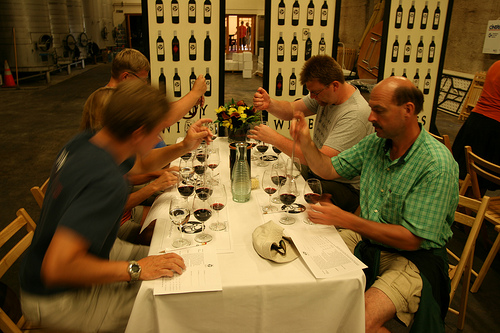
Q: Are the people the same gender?
A: No, they are both male and female.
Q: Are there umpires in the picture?
A: No, there are no umpires.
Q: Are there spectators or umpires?
A: No, there are no umpires or spectators.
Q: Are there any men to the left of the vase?
A: Yes, there is a man to the left of the vase.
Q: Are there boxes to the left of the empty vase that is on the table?
A: No, there is a man to the left of the vase.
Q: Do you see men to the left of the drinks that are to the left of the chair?
A: Yes, there is a man to the left of the drinks.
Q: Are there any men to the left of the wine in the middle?
A: Yes, there is a man to the left of the wine.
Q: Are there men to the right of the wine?
A: No, the man is to the left of the wine.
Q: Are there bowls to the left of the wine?
A: No, there is a man to the left of the wine.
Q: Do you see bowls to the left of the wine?
A: No, there is a man to the left of the wine.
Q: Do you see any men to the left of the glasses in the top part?
A: Yes, there is a man to the left of the glasses.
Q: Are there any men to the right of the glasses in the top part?
A: No, the man is to the left of the glasses.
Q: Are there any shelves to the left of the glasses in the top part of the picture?
A: No, there is a man to the left of the glasses.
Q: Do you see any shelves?
A: No, there are no shelves.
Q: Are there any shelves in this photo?
A: No, there are no shelves.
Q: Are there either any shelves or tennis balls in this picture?
A: No, there are no shelves or tennis balls.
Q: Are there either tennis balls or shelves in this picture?
A: No, there are no shelves or tennis balls.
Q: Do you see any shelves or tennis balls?
A: No, there are no shelves or tennis balls.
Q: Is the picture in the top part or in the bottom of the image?
A: The picture is in the top of the image.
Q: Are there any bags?
A: No, there are no bags.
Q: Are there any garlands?
A: No, there are no garlands.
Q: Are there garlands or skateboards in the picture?
A: No, there are no garlands or skateboards.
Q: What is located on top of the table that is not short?
A: The flowers are on top of the table.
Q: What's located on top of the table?
A: The flowers are on top of the table.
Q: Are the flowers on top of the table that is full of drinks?
A: Yes, the flowers are on top of the table.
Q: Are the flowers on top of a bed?
A: No, the flowers are on top of the table.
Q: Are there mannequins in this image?
A: No, there are no mannequins.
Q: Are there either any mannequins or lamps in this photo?
A: No, there are no mannequins or lamps.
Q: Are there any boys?
A: No, there are no boys.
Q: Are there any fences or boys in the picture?
A: No, there are no boys or fences.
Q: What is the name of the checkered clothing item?
A: The clothing item is a shirt.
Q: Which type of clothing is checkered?
A: The clothing is a shirt.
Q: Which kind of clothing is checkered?
A: The clothing is a shirt.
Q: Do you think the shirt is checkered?
A: Yes, the shirt is checkered.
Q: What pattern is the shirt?
A: The shirt is checkered.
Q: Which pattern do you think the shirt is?
A: The shirt is checkered.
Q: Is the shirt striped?
A: No, the shirt is checkered.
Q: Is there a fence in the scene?
A: No, there are no fences.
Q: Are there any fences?
A: No, there are no fences.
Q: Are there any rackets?
A: No, there are no rackets.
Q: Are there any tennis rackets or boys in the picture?
A: No, there are no tennis rackets or boys.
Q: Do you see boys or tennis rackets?
A: No, there are no tennis rackets or boys.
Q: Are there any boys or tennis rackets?
A: No, there are no tennis rackets or boys.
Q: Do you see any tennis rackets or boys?
A: No, there are no tennis rackets or boys.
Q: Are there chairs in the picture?
A: Yes, there is a chair.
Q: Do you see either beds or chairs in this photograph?
A: Yes, there is a chair.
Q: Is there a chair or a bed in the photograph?
A: Yes, there is a chair.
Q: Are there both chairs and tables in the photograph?
A: Yes, there are both a chair and a table.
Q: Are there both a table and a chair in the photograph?
A: Yes, there are both a chair and a table.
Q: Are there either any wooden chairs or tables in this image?
A: Yes, there is a wood chair.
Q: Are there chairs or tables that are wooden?
A: Yes, the chair is wooden.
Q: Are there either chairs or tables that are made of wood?
A: Yes, the chair is made of wood.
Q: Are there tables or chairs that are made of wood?
A: Yes, the chair is made of wood.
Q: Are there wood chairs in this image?
A: Yes, there is a wood chair.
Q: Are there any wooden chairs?
A: Yes, there is a wood chair.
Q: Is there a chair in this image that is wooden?
A: Yes, there is a chair that is wooden.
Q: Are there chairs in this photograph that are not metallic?
A: Yes, there is a wooden chair.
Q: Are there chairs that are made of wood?
A: Yes, there is a chair that is made of wood.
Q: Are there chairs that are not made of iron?
A: Yes, there is a chair that is made of wood.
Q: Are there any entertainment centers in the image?
A: No, there are no entertainment centers.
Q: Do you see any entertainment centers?
A: No, there are no entertainment centers.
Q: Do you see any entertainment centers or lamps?
A: No, there are no entertainment centers or lamps.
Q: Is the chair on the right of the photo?
A: Yes, the chair is on the right of the image.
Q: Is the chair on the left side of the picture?
A: No, the chair is on the right of the image.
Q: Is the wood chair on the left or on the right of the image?
A: The chair is on the right of the image.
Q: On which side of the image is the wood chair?
A: The chair is on the right of the image.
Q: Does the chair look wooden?
A: Yes, the chair is wooden.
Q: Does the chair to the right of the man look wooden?
A: Yes, the chair is wooden.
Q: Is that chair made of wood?
A: Yes, the chair is made of wood.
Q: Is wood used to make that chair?
A: Yes, the chair is made of wood.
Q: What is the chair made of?
A: The chair is made of wood.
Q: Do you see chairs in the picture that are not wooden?
A: No, there is a chair but it is wooden.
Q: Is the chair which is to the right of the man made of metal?
A: No, the chair is made of wood.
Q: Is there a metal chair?
A: No, there is a chair but it is made of wood.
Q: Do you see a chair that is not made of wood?
A: No, there is a chair but it is made of wood.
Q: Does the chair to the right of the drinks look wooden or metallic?
A: The chair is wooden.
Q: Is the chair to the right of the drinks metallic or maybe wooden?
A: The chair is wooden.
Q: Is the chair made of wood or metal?
A: The chair is made of wood.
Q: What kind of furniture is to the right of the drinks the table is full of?
A: The piece of furniture is a chair.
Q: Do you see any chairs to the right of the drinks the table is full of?
A: Yes, there is a chair to the right of the drinks.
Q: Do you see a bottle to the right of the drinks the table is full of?
A: No, there is a chair to the right of the drinks.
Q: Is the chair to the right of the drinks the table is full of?
A: Yes, the chair is to the right of the drinks.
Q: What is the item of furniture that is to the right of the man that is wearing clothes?
A: The piece of furniture is a chair.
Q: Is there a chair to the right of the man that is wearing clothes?
A: Yes, there is a chair to the right of the man.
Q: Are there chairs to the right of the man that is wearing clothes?
A: Yes, there is a chair to the right of the man.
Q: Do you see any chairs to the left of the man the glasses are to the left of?
A: No, the chair is to the right of the man.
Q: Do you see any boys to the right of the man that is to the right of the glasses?
A: No, there is a chair to the right of the man.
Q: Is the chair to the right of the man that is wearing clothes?
A: Yes, the chair is to the right of the man.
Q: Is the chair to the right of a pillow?
A: No, the chair is to the right of the man.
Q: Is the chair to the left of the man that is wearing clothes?
A: No, the chair is to the right of the man.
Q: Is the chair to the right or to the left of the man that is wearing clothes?
A: The chair is to the right of the man.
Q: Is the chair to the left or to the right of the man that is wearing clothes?
A: The chair is to the right of the man.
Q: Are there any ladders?
A: No, there are no ladders.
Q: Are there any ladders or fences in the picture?
A: No, there are no ladders or fences.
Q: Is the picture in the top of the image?
A: Yes, the picture is in the top of the image.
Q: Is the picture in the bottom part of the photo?
A: No, the picture is in the top of the image.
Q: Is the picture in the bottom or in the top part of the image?
A: The picture is in the top of the image.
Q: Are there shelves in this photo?
A: No, there are no shelves.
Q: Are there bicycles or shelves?
A: No, there are no shelves or bicycles.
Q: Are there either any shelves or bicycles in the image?
A: No, there are no shelves or bicycles.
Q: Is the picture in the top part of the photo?
A: Yes, the picture is in the top of the image.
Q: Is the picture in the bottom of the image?
A: No, the picture is in the top of the image.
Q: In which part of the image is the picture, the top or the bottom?
A: The picture is in the top of the image.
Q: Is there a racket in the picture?
A: No, there are no rackets.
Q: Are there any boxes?
A: No, there are no boxes.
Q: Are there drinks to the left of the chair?
A: Yes, there are drinks to the left of the chair.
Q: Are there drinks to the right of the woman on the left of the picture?
A: Yes, there are drinks to the right of the woman.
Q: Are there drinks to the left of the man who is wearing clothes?
A: Yes, there are drinks to the left of the man.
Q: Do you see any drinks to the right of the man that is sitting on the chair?
A: No, the drinks are to the left of the man.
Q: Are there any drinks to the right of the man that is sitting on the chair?
A: No, the drinks are to the left of the man.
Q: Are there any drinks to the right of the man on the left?
A: Yes, there are drinks to the right of the man.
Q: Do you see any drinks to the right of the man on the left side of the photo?
A: Yes, there are drinks to the right of the man.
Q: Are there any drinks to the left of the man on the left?
A: No, the drinks are to the right of the man.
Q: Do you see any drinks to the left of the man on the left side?
A: No, the drinks are to the right of the man.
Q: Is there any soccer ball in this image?
A: No, there are no soccer balls.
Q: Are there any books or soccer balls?
A: No, there are no soccer balls or books.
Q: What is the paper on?
A: The paper is on the table.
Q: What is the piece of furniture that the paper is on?
A: The piece of furniture is a table.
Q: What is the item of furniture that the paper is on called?
A: The piece of furniture is a table.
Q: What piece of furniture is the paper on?
A: The paper is on the table.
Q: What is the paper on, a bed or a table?
A: The paper is on a table.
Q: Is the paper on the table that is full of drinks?
A: Yes, the paper is on the table.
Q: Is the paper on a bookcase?
A: No, the paper is on the table.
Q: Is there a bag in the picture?
A: No, there are no bags.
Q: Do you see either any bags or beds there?
A: No, there are no bags or beds.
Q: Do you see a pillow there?
A: No, there are no pillows.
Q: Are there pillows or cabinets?
A: No, there are no pillows or cabinets.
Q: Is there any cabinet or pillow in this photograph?
A: No, there are no pillows or cabinets.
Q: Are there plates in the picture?
A: No, there are no plates.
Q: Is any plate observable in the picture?
A: No, there are no plates.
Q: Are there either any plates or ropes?
A: No, there are no plates or ropes.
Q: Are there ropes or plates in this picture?
A: No, there are no plates or ropes.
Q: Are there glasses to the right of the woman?
A: Yes, there are glasses to the right of the woman.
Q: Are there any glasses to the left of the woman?
A: No, the glasses are to the right of the woman.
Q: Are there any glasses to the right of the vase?
A: Yes, there are glasses to the right of the vase.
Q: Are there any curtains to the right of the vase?
A: No, there are glasses to the right of the vase.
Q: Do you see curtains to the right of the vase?
A: No, there are glasses to the right of the vase.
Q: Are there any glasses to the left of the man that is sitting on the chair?
A: Yes, there are glasses to the left of the man.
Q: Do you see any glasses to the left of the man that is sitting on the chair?
A: Yes, there are glasses to the left of the man.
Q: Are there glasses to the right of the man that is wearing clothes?
A: No, the glasses are to the left of the man.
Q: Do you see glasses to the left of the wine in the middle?
A: Yes, there are glasses to the left of the wine.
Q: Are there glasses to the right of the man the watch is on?
A: Yes, there are glasses to the right of the man.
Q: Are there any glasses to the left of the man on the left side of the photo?
A: No, the glasses are to the right of the man.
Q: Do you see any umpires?
A: No, there are no umpires.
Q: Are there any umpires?
A: No, there are no umpires.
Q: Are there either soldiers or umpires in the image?
A: No, there are no umpires or soldiers.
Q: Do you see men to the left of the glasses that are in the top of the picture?
A: Yes, there is a man to the left of the glasses.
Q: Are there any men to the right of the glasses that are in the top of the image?
A: No, the man is to the left of the glasses.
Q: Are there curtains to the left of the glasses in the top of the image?
A: No, there is a man to the left of the glasses.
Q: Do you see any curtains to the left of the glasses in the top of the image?
A: No, there is a man to the left of the glasses.